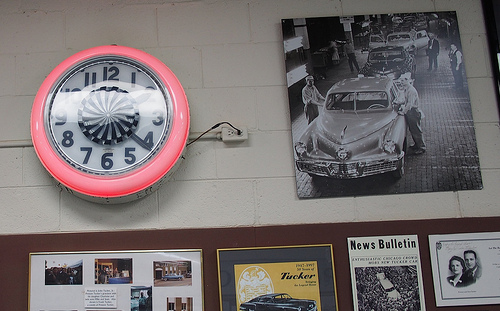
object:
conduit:
[0, 127, 249, 148]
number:
[62, 130, 74, 147]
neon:
[29, 44, 190, 206]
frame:
[215, 244, 344, 310]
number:
[101, 153, 114, 171]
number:
[80, 146, 93, 164]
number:
[124, 147, 136, 164]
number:
[103, 66, 120, 81]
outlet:
[222, 126, 248, 142]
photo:
[215, 244, 344, 310]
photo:
[345, 234, 427, 310]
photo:
[427, 231, 499, 308]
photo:
[28, 248, 206, 311]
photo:
[279, 10, 484, 201]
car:
[295, 74, 408, 180]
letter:
[350, 240, 357, 250]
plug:
[220, 125, 248, 143]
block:
[156, 178, 256, 231]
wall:
[0, 0, 498, 308]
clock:
[29, 44, 191, 205]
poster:
[278, 10, 485, 200]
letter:
[378, 239, 384, 249]